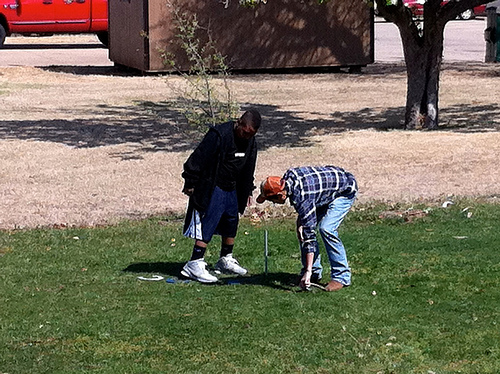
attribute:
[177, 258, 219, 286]
color — white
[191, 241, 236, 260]
socks — black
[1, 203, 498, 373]
grass — green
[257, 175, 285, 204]
cap — red, orange, white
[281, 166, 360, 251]
shirt — checkered, plaid, checked, blue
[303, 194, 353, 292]
jeans — blue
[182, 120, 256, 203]
jacket — black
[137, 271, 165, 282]
horseshoe — white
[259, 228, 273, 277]
pole — short, skinny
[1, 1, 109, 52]
vehicle — red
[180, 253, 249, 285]
shoes — white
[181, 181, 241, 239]
shorts — blue, long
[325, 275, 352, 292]
shoe — brown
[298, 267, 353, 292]
boots — brown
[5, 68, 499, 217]
grass — brown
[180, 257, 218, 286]
sneaker — white, high top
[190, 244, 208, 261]
sock — black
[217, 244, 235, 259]
sock — black